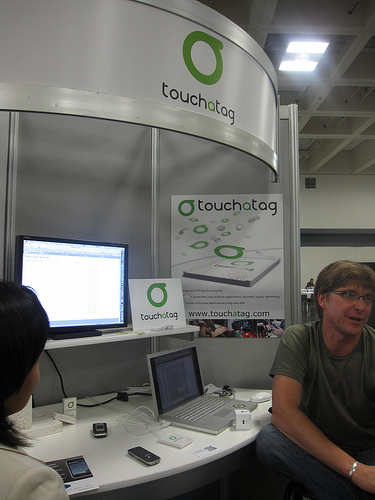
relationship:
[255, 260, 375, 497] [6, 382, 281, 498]
man sitting at desk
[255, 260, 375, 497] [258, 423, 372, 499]
man with leg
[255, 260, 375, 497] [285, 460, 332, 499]
man with leg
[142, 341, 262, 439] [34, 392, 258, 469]
laptop sitting on deks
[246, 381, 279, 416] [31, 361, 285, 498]
mouse lying on desk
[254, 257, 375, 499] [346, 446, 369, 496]
man wearing bracelet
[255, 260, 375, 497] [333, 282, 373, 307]
man wearing eyeglasses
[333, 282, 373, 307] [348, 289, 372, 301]
eyeglasses over eyes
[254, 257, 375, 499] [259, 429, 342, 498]
man wearing jeans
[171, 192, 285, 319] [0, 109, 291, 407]
advertising sign hanging on wall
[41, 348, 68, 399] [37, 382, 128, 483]
long cord on desk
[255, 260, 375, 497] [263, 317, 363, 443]
man in shirt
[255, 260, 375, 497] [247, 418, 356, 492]
man in jeans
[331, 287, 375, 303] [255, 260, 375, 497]
eyeglasses on man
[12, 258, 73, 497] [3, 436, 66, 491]
woman wears jacket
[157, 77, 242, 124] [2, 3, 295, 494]
touchatag on display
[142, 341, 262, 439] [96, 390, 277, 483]
laptop on desk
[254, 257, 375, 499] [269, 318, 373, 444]
man wears shirt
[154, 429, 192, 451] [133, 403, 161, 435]
touch pad has cord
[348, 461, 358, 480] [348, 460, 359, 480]
bracelet on bracelet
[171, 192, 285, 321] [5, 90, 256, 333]
advertising sign on wall